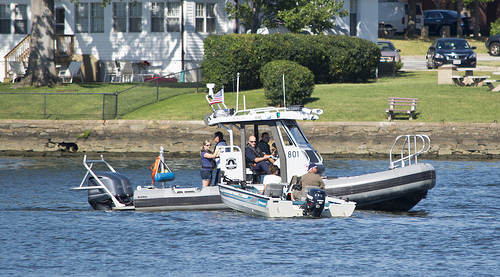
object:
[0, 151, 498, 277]
water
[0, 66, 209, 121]
fence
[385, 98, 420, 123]
bench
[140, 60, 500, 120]
grass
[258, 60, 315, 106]
bush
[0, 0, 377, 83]
house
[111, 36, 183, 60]
siding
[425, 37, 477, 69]
car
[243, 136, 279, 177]
man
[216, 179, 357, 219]
boat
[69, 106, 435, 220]
boat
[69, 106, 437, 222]
boats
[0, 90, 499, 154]
bank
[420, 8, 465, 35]
car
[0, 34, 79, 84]
rails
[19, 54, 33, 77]
steps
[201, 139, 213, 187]
woman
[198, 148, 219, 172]
purple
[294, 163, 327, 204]
man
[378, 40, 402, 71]
car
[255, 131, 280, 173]
men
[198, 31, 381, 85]
hedges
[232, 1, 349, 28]
leaves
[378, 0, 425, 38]
vehicles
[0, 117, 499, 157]
wall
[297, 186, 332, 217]
engine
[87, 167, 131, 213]
engine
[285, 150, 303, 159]
801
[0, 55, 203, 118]
yard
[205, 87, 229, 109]
flag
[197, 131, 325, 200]
people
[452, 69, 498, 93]
tables